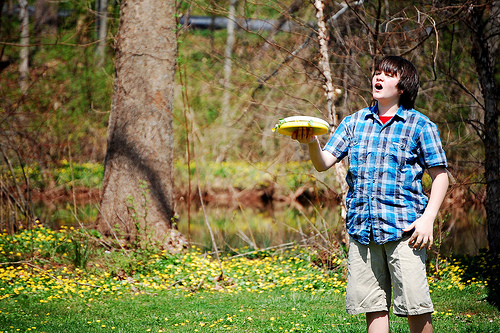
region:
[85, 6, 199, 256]
the trunk of a tree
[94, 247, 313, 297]
yellow wild flowers at the base of a tree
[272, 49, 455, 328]
a boy holding a yellow frisbee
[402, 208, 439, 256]
the hand of a boy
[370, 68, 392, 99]
the face of a boy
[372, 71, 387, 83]
the nose of a boy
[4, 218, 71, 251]
yellow wild flowers in the woods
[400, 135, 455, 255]
an arm of a boy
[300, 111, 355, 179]
the arm of a boy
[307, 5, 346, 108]
a trunk of a tree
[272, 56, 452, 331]
teenage holding two frisbees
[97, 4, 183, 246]
large brown tree trunk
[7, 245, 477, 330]
green grass with yellow flowers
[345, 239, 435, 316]
beige shorts on the boy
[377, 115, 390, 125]
red t-shirt under blue shirt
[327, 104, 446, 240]
blue plaid shirt with short sleeves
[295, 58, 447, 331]
teen boy with long hair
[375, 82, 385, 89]
teen's open mouth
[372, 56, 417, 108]
teen's long brown hair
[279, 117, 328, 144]
two Frisbees in right hand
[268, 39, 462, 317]
a boy holding two frisbees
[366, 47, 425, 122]
a boy with black hair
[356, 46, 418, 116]
the head of a boy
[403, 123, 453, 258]
the arm of a boy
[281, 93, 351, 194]
the arm of a boy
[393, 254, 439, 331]
the leg of a boy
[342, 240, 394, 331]
the leg of a boy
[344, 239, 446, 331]
the legs of a boy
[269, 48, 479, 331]
a boy holding two frisbees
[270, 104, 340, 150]
two yellow frisbees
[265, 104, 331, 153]
a hand holding two frisbees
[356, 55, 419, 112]
the head of a boy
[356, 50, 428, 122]
a boy with his mouth open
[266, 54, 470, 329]
a boy wearing a blue shirt and tan shorts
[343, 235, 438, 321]
a pair of tan shorts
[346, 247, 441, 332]
the legs of a boy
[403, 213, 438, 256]
the hand of a boy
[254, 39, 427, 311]
boy holding the frisbee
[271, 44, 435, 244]
boy holding the frisbee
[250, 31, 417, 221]
boy holding the frisbee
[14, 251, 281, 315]
the flowers are yellow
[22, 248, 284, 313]
the flowers are yellow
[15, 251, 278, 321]
the flowers are yellow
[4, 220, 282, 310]
the flowers are yellow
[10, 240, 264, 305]
the flowers are yellow